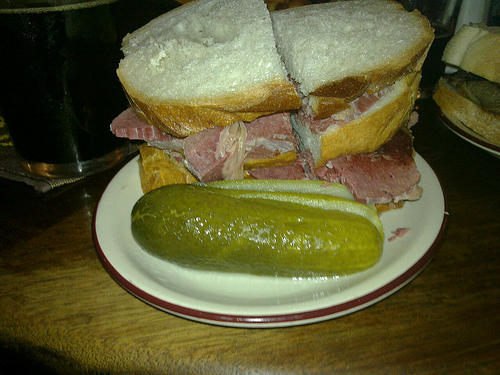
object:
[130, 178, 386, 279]
dill pickle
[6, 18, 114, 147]
soda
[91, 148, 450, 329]
lunch plate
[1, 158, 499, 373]
table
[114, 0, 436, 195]
sandwich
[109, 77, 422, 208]
meat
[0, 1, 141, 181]
drink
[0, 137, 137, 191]
coaster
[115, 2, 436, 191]
bread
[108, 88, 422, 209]
ham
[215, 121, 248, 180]
fat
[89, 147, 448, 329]
stripe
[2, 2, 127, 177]
glass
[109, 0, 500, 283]
food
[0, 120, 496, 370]
desk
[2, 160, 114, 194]
tablecloth